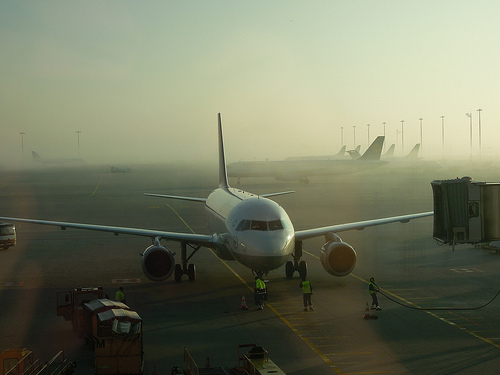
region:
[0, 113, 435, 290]
a plane sits on a runway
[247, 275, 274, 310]
a worker is in front of the plane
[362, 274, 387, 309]
a worker is dragging a hose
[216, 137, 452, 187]
more planes are in the background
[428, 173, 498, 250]
a walkway is next to the plane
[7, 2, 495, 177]
the sky is very misty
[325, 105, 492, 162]
a row if lights behind the plane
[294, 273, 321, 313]
a worker wears a reflective vest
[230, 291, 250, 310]
a traffic cone is on the ground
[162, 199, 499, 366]
the plane is between two yellow lines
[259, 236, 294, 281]
nose of the aircraft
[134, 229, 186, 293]
engine of the aircraft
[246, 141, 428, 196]
parked airplanes in the fog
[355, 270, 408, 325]
man holding a rope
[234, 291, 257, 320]
cones in front of the airplane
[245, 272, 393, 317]
men wearing reflectors on their clothes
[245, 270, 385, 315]
men in front of the airplane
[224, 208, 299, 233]
front windows of the airplane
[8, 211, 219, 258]
wing of the airplane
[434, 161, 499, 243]
entryway to the airplane's terminal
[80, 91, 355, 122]
heavy fog in the horizon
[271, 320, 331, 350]
long yellow line on the ground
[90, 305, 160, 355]
large orange container wagon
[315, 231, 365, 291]
large plane wing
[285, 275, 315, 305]
bright yellow vest on worker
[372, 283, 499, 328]
large black cord on ground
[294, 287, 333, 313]
man wearing black pants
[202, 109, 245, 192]
long silver airplane tail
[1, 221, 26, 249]
back of large truck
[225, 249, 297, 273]
gray bottom of airplane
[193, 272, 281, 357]
shadow is cast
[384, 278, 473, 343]
the runway lines are yellow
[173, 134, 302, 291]
the plane is reflecting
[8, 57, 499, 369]
it is sunny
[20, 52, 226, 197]
the sky is covered by clouds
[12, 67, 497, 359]
this is an airport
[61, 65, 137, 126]
the clouds are grey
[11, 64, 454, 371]
it is a daytime scene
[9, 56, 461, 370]
it is an outdoor scene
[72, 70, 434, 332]
the plane is not moving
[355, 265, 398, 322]
person wearing a green vest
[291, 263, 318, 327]
person wearing a green vest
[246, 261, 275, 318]
person wearing a green vest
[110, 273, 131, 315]
person wearing a green vest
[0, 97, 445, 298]
a large passenger airplane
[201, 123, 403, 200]
a large passenger airplane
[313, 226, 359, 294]
a large airplane engine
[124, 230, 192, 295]
a large airplane engine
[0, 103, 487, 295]
large airplane sitting on a runway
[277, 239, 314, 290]
large rubber airplane landing gear